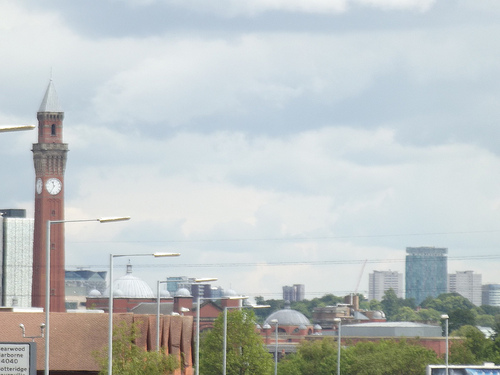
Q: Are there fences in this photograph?
A: No, there are no fences.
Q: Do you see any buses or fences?
A: No, there are no fences or buses.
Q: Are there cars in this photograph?
A: No, there are no cars.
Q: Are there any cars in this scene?
A: No, there are no cars.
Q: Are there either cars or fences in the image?
A: No, there are no cars or fences.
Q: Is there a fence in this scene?
A: No, there are no fences.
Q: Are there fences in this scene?
A: No, there are no fences.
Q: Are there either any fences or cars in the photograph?
A: No, there are no fences or cars.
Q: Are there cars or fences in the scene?
A: No, there are no fences or cars.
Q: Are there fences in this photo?
A: No, there are no fences.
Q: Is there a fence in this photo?
A: No, there are no fences.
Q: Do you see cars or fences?
A: No, there are no fences or cars.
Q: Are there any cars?
A: No, there are no cars.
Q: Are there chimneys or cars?
A: No, there are no cars or chimneys.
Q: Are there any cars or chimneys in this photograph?
A: No, there are no cars or chimneys.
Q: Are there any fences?
A: No, there are no fences.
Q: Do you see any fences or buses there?
A: No, there are no fences or buses.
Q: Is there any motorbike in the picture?
A: No, there are no motorcycles.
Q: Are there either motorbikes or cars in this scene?
A: No, there are no motorbikes or cars.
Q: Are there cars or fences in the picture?
A: No, there are no cars or fences.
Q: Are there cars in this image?
A: No, there are no cars.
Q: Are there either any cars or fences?
A: No, there are no cars or fences.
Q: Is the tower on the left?
A: Yes, the tower is on the left of the image.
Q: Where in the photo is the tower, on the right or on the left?
A: The tower is on the left of the image.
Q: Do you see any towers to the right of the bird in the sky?
A: Yes, there is a tower to the right of the bird.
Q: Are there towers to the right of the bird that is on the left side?
A: Yes, there is a tower to the right of the bird.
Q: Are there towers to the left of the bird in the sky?
A: No, the tower is to the right of the bird.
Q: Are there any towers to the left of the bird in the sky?
A: No, the tower is to the right of the bird.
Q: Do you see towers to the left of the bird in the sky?
A: No, the tower is to the right of the bird.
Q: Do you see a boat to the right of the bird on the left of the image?
A: No, there is a tower to the right of the bird.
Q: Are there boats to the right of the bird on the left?
A: No, there is a tower to the right of the bird.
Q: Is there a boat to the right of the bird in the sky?
A: No, there is a tower to the right of the bird.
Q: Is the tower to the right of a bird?
A: Yes, the tower is to the right of a bird.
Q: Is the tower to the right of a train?
A: No, the tower is to the right of a bird.